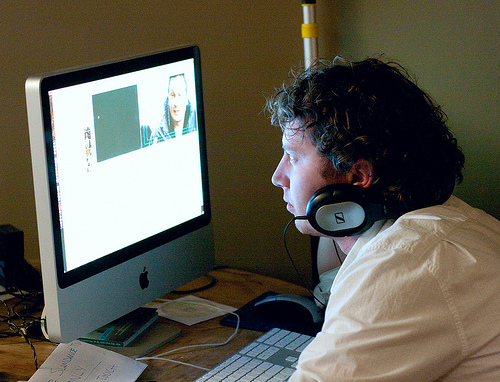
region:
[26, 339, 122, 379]
Paper on a desk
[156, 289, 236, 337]
CD on a desk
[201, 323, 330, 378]
Keyboard on a desk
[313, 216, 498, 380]
White shirt on a man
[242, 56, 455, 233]
Brown hair on a man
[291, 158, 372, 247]
Headphones on a man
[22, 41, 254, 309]
Computer screen in a room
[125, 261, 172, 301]
Apple on a moniter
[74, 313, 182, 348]
Book on a desk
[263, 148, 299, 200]
Nose on a face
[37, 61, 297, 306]
the monitor is on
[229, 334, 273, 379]
the keyboard is white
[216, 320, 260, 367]
the keyboard is white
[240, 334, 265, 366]
the keyboard is white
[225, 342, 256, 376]
the keyboard is white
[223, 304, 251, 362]
the keyboard is white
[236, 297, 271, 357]
the keyboard is white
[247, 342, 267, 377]
the keyboard is white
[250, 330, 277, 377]
the keyboard is white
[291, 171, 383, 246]
a headphone below man's ear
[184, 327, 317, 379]
a white computer keyboard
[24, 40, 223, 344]
an Apple monitor on the desk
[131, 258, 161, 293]
Apple logo on monitor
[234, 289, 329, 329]
mouse on a mouse pad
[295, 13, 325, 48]
a yellow piece of plastic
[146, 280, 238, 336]
a plastic disc container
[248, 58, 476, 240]
man with curly hair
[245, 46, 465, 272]
man focused on his montor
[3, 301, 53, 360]
wires connecting components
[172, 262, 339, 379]
the keyboard is white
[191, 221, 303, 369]
the keyboard is white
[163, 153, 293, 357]
the keyboard is white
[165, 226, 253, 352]
the keyboard is white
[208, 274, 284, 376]
the keyboard is white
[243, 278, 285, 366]
the keyboard is white